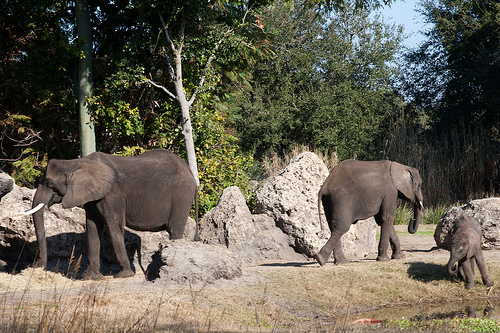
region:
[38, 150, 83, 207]
the head of an elephant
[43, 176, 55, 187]
the eye of an elephant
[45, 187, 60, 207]
the mouth of an elephant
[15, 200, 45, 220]
the tusk of an elephant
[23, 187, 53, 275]
the trunk of an elephant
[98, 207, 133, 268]
the leg of an elephant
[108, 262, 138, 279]
the foot of an elephant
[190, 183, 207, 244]
the tail of an elephant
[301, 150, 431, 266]
a gray elephant on the ground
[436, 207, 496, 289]
a baby elephant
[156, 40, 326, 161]
the grass is green and visible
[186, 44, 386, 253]
the grass is green and visible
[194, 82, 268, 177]
the grass is green and visible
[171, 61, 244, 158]
the grass is green and visible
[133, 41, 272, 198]
the grass is green and visible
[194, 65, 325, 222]
the grass is green and visible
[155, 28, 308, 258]
the grass is green and visible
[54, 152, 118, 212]
the ear of an elephant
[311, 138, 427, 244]
elephant on the ground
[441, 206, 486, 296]
baby elephant next to adult one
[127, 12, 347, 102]
trees next to the elephants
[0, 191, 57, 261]
trunk of the elephant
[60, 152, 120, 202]
ear of the elephant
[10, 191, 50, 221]
tusk of the elephant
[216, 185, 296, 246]
rocks next to the elephant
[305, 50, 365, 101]
leaves on the tree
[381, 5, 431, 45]
blue sky above land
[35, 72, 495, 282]
three different elephants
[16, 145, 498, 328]
elephants in the zoo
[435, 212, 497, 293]
a baby elephant in the zoo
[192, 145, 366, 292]
a large rock behind the elephant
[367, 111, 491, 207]
dead grass behind the elephant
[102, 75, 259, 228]
the tree leaves are yellow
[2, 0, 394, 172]
trees behind the elephant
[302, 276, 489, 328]
a pool by the elephants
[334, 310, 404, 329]
something red in the water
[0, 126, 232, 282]
elephant between the rocks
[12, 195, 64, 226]
the elephant tusk is ivory